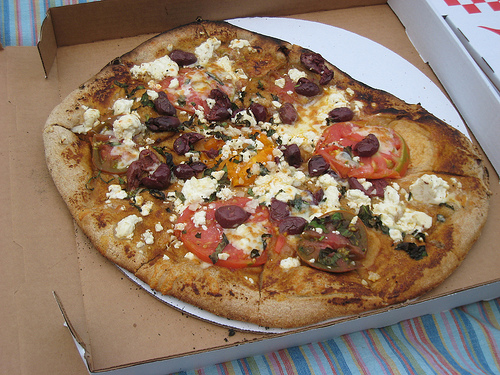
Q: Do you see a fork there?
A: No, there are no forks.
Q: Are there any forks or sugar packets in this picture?
A: No, there are no forks or sugar packets.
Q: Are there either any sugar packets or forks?
A: No, there are no forks or sugar packets.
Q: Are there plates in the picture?
A: Yes, there is a plate.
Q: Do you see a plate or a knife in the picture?
A: Yes, there is a plate.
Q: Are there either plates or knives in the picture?
A: Yes, there is a plate.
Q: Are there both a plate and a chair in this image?
A: No, there is a plate but no chairs.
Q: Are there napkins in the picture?
A: No, there are no napkins.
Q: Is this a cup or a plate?
A: This is a plate.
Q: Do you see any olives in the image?
A: Yes, there are olives.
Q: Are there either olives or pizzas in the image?
A: Yes, there are olives.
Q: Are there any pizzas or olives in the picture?
A: Yes, there are olives.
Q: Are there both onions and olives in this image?
A: No, there are olives but no onions.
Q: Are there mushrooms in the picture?
A: No, there are no mushrooms.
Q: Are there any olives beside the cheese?
A: Yes, there are olives beside the cheese.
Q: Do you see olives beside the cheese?
A: Yes, there are olives beside the cheese.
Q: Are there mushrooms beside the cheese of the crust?
A: No, there are olives beside the cheese.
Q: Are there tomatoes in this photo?
A: Yes, there is a tomato.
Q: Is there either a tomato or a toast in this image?
A: Yes, there is a tomato.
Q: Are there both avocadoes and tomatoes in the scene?
A: No, there is a tomato but no avocadoes.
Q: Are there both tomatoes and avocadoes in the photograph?
A: No, there is a tomato but no avocadoes.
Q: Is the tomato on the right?
A: Yes, the tomato is on the right of the image.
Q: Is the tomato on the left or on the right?
A: The tomato is on the right of the image.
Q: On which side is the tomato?
A: The tomato is on the right of the image.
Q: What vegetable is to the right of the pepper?
A: The vegetable is a tomato.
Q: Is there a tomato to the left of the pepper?
A: No, the tomato is to the right of the pepper.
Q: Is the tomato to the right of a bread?
A: No, the tomato is to the right of the pepper.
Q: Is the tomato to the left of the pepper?
A: No, the tomato is to the right of the pepper.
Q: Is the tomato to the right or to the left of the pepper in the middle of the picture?
A: The tomato is to the right of the pepper.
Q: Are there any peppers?
A: Yes, there is a pepper.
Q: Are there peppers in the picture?
A: Yes, there is a pepper.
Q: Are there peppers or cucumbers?
A: Yes, there is a pepper.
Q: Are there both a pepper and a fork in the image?
A: No, there is a pepper but no forks.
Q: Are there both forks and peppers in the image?
A: No, there is a pepper but no forks.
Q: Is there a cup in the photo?
A: No, there are no cups.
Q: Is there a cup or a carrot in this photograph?
A: No, there are no cups or carrots.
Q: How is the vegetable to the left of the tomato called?
A: The vegetable is a pepper.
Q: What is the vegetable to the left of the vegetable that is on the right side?
A: The vegetable is a pepper.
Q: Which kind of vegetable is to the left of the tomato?
A: The vegetable is a pepper.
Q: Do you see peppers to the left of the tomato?
A: Yes, there is a pepper to the left of the tomato.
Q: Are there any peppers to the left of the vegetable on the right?
A: Yes, there is a pepper to the left of the tomato.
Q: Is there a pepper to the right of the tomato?
A: No, the pepper is to the left of the tomato.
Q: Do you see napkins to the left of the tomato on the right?
A: No, there is a pepper to the left of the tomato.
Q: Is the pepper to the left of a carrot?
A: No, the pepper is to the left of a tomato.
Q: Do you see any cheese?
A: Yes, there is cheese.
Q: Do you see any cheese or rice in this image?
A: Yes, there is cheese.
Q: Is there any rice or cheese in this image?
A: Yes, there is cheese.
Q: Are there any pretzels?
A: No, there are no pretzels.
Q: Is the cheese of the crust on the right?
A: Yes, the cheese is on the right of the image.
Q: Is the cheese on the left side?
A: No, the cheese is on the right of the image.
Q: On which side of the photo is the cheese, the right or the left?
A: The cheese is on the right of the image.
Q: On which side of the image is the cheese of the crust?
A: The cheese is on the right of the image.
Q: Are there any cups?
A: No, there are no cups.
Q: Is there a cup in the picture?
A: No, there are no cups.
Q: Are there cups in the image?
A: No, there are no cups.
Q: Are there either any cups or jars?
A: No, there are no cups or jars.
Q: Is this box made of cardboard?
A: Yes, the box is made of cardboard.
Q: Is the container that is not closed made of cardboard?
A: Yes, the box is made of cardboard.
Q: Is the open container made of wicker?
A: No, the box is made of cardboard.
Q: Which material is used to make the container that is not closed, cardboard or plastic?
A: The box is made of cardboard.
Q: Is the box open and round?
A: Yes, the box is open and round.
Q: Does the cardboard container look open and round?
A: Yes, the box is open and round.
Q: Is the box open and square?
A: No, the box is open but round.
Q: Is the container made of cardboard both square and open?
A: No, the box is open but round.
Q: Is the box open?
A: Yes, the box is open.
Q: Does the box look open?
A: Yes, the box is open.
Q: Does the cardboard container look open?
A: Yes, the box is open.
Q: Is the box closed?
A: No, the box is open.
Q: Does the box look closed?
A: No, the box is open.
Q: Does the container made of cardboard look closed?
A: No, the box is open.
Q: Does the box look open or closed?
A: The box is open.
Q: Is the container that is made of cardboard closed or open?
A: The box is open.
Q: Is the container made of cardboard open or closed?
A: The box is open.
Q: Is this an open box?
A: Yes, this is an open box.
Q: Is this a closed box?
A: No, this is an open box.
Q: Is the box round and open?
A: Yes, the box is round and open.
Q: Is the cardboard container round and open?
A: Yes, the box is round and open.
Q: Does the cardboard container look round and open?
A: Yes, the box is round and open.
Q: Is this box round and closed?
A: No, the box is round but open.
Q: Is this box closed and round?
A: No, the box is round but open.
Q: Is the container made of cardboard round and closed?
A: No, the box is round but open.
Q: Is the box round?
A: Yes, the box is round.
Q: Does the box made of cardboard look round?
A: Yes, the box is round.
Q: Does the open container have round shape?
A: Yes, the box is round.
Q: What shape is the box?
A: The box is round.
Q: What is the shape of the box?
A: The box is round.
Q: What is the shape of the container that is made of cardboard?
A: The box is round.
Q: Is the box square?
A: No, the box is round.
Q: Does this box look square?
A: No, the box is round.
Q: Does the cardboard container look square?
A: No, the box is round.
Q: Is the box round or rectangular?
A: The box is round.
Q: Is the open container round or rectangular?
A: The box is round.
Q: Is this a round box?
A: Yes, this is a round box.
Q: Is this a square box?
A: No, this is a round box.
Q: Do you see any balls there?
A: No, there are no balls.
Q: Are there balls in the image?
A: No, there are no balls.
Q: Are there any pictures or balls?
A: No, there are no balls or pictures.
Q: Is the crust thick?
A: Yes, the crust is thick.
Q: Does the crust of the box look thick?
A: Yes, the crust is thick.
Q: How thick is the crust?
A: The crust is thick.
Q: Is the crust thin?
A: No, the crust is thick.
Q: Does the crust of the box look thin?
A: No, the crust is thick.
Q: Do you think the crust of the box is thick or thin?
A: The crust is thick.